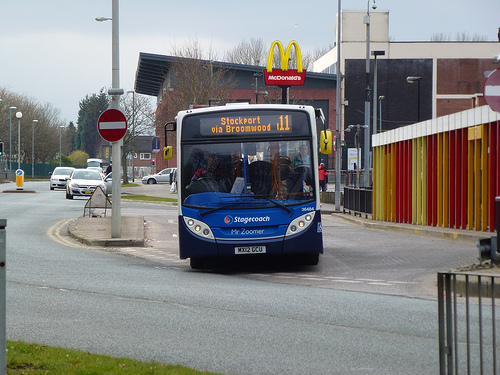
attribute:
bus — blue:
[169, 101, 330, 272]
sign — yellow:
[261, 37, 313, 90]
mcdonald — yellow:
[267, 73, 302, 82]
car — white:
[67, 162, 110, 199]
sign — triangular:
[80, 185, 113, 212]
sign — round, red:
[93, 105, 132, 143]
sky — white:
[36, 31, 81, 91]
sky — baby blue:
[393, 7, 490, 30]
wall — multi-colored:
[372, 140, 495, 234]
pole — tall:
[101, 5, 127, 239]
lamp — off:
[11, 108, 34, 123]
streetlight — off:
[89, 13, 114, 39]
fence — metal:
[428, 270, 498, 375]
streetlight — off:
[404, 72, 430, 86]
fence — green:
[33, 161, 54, 179]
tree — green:
[75, 90, 101, 152]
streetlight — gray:
[93, 10, 116, 27]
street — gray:
[101, 278, 286, 362]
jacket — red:
[315, 167, 331, 183]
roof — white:
[334, 10, 499, 61]